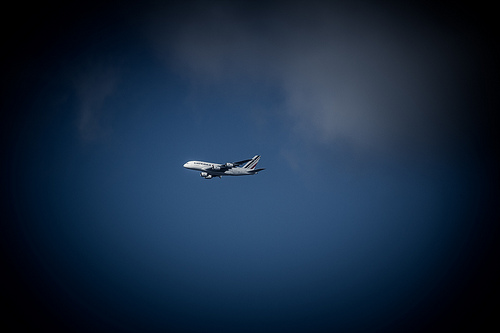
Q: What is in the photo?
A: A plane.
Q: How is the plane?
A: In motion.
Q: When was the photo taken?
A: Night.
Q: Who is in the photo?
A: No one.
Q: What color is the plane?
A: White.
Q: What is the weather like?
A: Cloudy.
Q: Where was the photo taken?
A: In the sky.